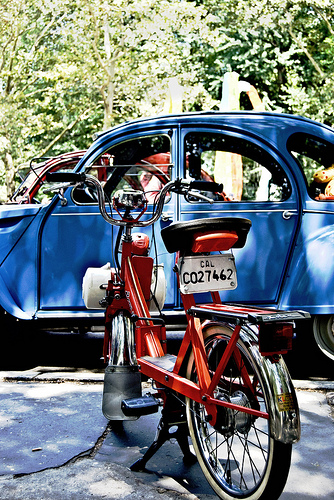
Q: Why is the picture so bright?
A: The sun is shining.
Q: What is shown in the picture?
A: A scooter.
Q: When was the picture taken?
A: At daytime.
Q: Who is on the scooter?
A: Nobody.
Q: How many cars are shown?
A: Two.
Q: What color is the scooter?
A: Red.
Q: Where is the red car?
A: Behind the blue one.